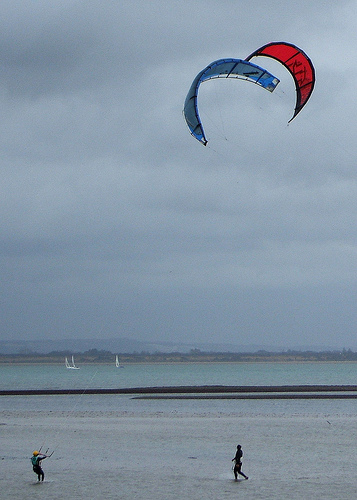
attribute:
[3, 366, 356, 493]
water — shallow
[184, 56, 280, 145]
kite — blue, large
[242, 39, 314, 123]
kite — red, large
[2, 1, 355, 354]
sky — cloudy, dark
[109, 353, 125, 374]
boat — sailing, white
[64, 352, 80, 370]
boat — sailing, white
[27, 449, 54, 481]
man — getting ready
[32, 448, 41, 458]
helmet — yellow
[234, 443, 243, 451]
hair — dark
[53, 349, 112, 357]
vegetation — green